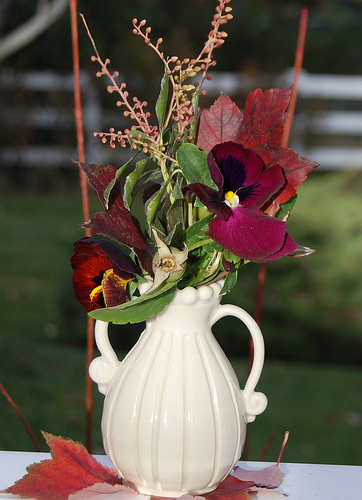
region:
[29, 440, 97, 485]
this is a flower petal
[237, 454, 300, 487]
this is a flower petal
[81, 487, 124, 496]
this is a flower petal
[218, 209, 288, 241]
this is a flower petal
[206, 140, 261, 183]
this is a flower petal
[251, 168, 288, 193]
this is a flower petal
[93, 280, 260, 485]
this is a vase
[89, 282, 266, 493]
this is a white vase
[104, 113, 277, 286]
these are beautiful flowers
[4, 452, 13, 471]
this is a table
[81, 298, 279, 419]
handles on the white vase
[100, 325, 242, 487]
grooves in the white vase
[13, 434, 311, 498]
leaves under the vase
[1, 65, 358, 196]
white fence in the distance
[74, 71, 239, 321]
green leaves of the flowers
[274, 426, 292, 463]
stem of the red leaf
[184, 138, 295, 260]
purple petals of the flower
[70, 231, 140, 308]
dark red petals of the flower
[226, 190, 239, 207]
yellow and white center of purple flower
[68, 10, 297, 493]
white vase holding a flower arrangement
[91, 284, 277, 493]
vase with two handles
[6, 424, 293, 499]
red leaves vase is sitting on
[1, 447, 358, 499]
white table vase is sitting on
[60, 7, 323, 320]
flower arrangement in the vase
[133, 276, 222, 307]
lip of the white vase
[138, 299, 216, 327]
short neck of the vase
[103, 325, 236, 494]
grooved body of the vase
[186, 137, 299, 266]
purple flowers in the white vase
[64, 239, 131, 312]
dark red flower wtih yellow edges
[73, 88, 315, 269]
red leaves in the vase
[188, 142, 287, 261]
a pink and purple flower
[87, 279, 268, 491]
a white vase with a handle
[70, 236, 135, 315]
a dark red and yellow flower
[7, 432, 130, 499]
a red and yellow leaf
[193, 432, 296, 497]
a red and yellow leaf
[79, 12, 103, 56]
thin tip of a stem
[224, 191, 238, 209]
yellow and white center of a flower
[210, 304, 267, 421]
handle on a vase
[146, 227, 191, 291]
a budding flower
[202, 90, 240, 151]
a red leaf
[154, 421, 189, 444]
white grooves on vase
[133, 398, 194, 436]
white color on vase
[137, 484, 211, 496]
base on the vase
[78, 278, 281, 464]
large white vase on the surface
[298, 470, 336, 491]
white color on the surface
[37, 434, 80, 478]
cranberry color leaves on the table top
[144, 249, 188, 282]
white flowers in the vase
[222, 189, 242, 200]
tiny yellow flower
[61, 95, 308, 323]
beautiful flowers in vase